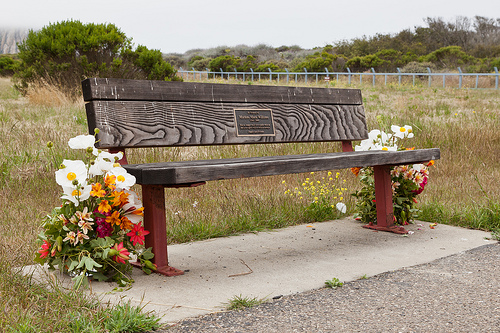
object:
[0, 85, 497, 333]
grass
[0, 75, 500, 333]
field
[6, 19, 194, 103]
bush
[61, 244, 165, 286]
leaves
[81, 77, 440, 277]
bench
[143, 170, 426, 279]
metal legs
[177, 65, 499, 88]
fence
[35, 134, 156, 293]
bouquet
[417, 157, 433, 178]
ground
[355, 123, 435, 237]
flowers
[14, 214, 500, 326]
cement platform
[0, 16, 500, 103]
trees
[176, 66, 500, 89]
bent poles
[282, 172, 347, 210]
flower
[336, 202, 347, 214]
flower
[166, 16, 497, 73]
treeline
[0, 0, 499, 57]
sky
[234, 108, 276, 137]
plaque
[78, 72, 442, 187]
wood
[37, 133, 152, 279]
flower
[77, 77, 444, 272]
seat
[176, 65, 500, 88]
poles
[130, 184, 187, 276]
leg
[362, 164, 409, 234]
leg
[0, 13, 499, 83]
background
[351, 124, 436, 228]
bouquet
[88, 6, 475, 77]
cover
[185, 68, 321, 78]
line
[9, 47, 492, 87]
horizon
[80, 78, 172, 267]
side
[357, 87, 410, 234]
side